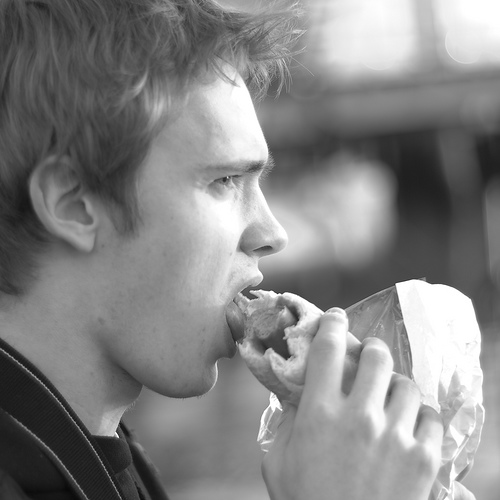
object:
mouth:
[217, 267, 268, 362]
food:
[229, 277, 365, 418]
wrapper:
[344, 259, 498, 484]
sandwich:
[232, 281, 486, 424]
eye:
[208, 169, 250, 194]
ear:
[23, 148, 100, 255]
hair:
[1, 12, 309, 273]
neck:
[20, 344, 163, 447]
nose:
[237, 176, 286, 263]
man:
[2, 3, 482, 498]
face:
[20, 3, 297, 404]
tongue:
[218, 297, 256, 341]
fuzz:
[108, 378, 136, 400]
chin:
[135, 359, 225, 405]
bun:
[228, 288, 487, 499]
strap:
[12, 365, 148, 496]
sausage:
[232, 280, 302, 355]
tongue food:
[208, 281, 497, 407]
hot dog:
[242, 288, 384, 413]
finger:
[304, 305, 349, 410]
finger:
[353, 325, 392, 410]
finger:
[390, 371, 417, 426]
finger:
[418, 400, 444, 460]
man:
[8, 7, 284, 464]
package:
[345, 279, 481, 499]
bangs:
[180, 6, 347, 109]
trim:
[4, 344, 44, 387]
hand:
[247, 317, 464, 498]